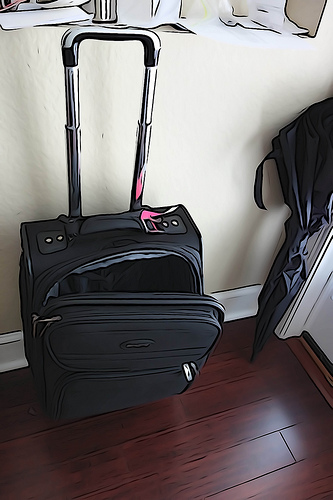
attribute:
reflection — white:
[134, 164, 146, 201]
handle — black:
[55, 15, 173, 239]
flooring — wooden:
[1, 315, 331, 498]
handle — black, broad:
[267, 90, 332, 230]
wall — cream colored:
[0, 0, 333, 334]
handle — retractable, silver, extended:
[55, 19, 159, 208]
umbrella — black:
[238, 92, 327, 364]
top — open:
[19, 205, 221, 321]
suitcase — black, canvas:
[22, 202, 228, 421]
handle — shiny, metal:
[61, 25, 163, 218]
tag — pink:
[142, 203, 180, 221]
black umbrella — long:
[251, 87, 331, 369]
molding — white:
[2, 283, 263, 374]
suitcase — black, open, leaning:
[19, 22, 225, 428]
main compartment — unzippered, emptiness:
[44, 247, 224, 419]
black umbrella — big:
[246, 97, 330, 364]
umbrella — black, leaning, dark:
[244, 86, 331, 369]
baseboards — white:
[1, 270, 273, 377]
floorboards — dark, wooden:
[3, 301, 332, 496]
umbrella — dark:
[262, 121, 318, 489]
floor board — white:
[205, 291, 264, 332]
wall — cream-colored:
[131, 46, 283, 331]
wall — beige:
[1, 1, 331, 249]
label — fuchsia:
[141, 204, 179, 222]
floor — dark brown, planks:
[1, 315, 331, 499]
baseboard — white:
[218, 285, 262, 324]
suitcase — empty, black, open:
[25, 17, 288, 495]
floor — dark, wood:
[5, 321, 316, 496]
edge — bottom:
[0, 15, 321, 37]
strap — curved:
[244, 152, 277, 218]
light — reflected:
[204, 394, 321, 498]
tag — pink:
[139, 210, 179, 221]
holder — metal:
[62, 22, 162, 218]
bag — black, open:
[16, 200, 228, 418]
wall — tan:
[84, 82, 319, 233]